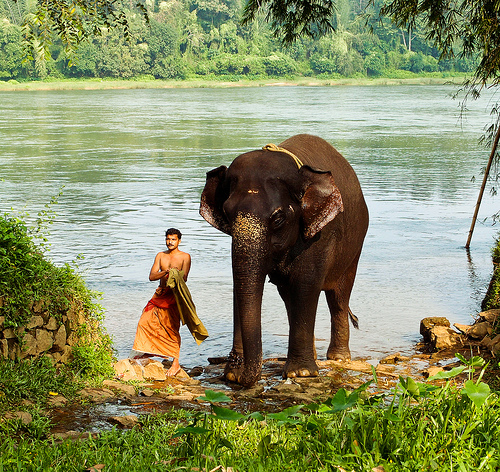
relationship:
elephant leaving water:
[198, 134, 368, 390] [4, 89, 498, 359]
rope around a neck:
[261, 142, 303, 169] [262, 130, 310, 165]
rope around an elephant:
[261, 142, 303, 169] [198, 134, 368, 390]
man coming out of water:
[132, 227, 191, 377] [1, 90, 493, 275]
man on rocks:
[132, 227, 191, 375] [110, 359, 199, 386]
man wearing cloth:
[132, 227, 191, 377] [138, 282, 191, 357]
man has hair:
[132, 227, 191, 377] [163, 226, 183, 238]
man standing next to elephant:
[132, 227, 191, 377] [198, 134, 368, 390]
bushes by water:
[144, 18, 189, 81] [1, 81, 498, 432]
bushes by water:
[384, 51, 440, 71] [1, 81, 498, 432]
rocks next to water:
[108, 413, 140, 427] [1, 81, 498, 432]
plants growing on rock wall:
[3, 220, 99, 410] [0, 187, 194, 426]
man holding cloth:
[132, 227, 191, 377] [167, 268, 209, 345]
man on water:
[132, 227, 191, 377] [1, 81, 498, 432]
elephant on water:
[198, 134, 368, 390] [1, 81, 498, 432]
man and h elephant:
[132, 227, 191, 377] [195, 108, 368, 393]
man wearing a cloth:
[132, 227, 191, 375] [132, 286, 182, 358]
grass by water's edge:
[169, 388, 243, 470] [23, 319, 475, 445]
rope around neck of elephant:
[253, 126, 306, 172] [173, 84, 418, 343]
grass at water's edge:
[1, 339, 499, 469] [68, 285, 480, 377]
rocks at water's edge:
[108, 413, 140, 427] [92, 305, 486, 406]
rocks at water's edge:
[350, 357, 397, 377] [92, 305, 486, 406]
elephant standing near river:
[191, 127, 379, 388] [0, 86, 499, 435]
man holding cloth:
[132, 227, 191, 377] [169, 269, 209, 340]